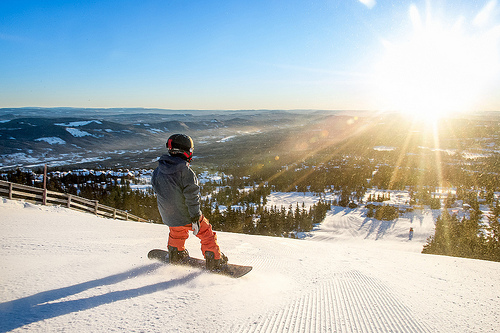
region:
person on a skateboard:
[80, 60, 266, 285]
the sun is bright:
[354, 18, 473, 129]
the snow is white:
[416, 275, 494, 319]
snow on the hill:
[308, 234, 418, 296]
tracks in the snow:
[14, 228, 97, 268]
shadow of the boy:
[0, 271, 145, 323]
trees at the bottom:
[347, 190, 412, 227]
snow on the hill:
[7, 93, 90, 154]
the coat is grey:
[157, 177, 181, 221]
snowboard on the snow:
[144, 243, 249, 282]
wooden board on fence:
[5, 179, 15, 201]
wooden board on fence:
[40, 188, 47, 207]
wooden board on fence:
[65, 192, 74, 209]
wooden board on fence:
[91, 198, 100, 218]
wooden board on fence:
[111, 208, 118, 222]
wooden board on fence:
[124, 211, 131, 220]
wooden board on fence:
[11, 186, 43, 198]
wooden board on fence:
[46, 194, 68, 206]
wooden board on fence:
[69, 198, 94, 210]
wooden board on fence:
[0, 187, 12, 194]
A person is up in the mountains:
[10, 57, 495, 330]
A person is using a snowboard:
[15, 70, 410, 330]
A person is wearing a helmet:
[10, 61, 375, 318]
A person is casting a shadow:
[10, 70, 325, 315]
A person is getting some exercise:
[0, 55, 395, 325]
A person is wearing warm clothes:
[15, 56, 410, 321]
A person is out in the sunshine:
[27, 56, 472, 317]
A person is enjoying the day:
[12, 24, 419, 332]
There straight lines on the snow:
[271, 268, 403, 331]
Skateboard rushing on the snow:
[142, 244, 248, 285]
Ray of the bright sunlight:
[339, 115, 451, 178]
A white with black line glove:
[187, 219, 205, 240]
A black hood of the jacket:
[147, 148, 191, 174]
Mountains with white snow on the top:
[54, 110, 108, 141]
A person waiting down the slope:
[400, 222, 424, 242]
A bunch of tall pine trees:
[256, 151, 353, 183]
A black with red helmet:
[162, 131, 199, 161]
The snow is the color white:
[268, 242, 462, 323]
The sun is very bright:
[377, 28, 486, 140]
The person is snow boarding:
[131, 112, 270, 289]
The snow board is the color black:
[148, 240, 256, 282]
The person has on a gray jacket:
[146, 151, 204, 230]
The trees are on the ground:
[231, 133, 495, 256]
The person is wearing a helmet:
[161, 124, 200, 165]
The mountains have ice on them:
[31, 95, 115, 166]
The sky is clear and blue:
[16, 2, 296, 96]